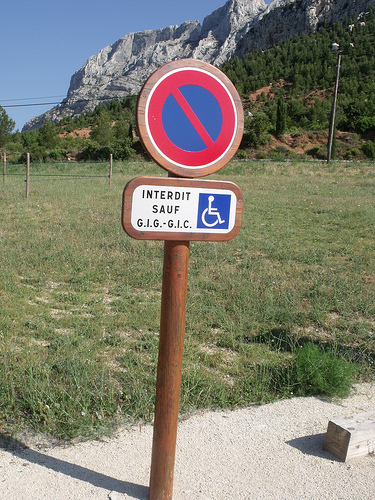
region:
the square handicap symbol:
[196, 187, 235, 231]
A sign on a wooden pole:
[99, 46, 254, 498]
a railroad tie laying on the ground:
[313, 386, 369, 464]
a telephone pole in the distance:
[312, 40, 346, 171]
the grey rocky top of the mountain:
[58, 15, 241, 75]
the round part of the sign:
[122, 48, 258, 178]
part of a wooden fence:
[3, 150, 118, 199]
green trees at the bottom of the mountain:
[262, 45, 325, 123]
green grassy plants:
[257, 324, 344, 397]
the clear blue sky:
[9, 14, 70, 78]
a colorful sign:
[122, 54, 248, 499]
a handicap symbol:
[198, 191, 231, 229]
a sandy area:
[214, 423, 317, 487]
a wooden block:
[322, 411, 373, 465]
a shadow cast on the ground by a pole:
[22, 444, 144, 499]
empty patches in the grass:
[209, 335, 236, 380]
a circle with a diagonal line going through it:
[133, 56, 244, 177]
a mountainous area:
[73, 6, 316, 43]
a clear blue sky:
[3, 3, 71, 81]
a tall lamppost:
[317, 36, 355, 161]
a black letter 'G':
[135, 217, 146, 228]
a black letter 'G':
[166, 218, 175, 228]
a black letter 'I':
[140, 189, 147, 197]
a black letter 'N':
[148, 189, 154, 198]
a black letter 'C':
[182, 218, 189, 231]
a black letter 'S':
[150, 201, 159, 214]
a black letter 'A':
[159, 205, 165, 214]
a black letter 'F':
[173, 205, 181, 213]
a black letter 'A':
[158, 201, 167, 213]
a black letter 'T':
[184, 191, 192, 200]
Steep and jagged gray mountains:
[71, 0, 322, 58]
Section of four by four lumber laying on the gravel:
[320, 404, 373, 464]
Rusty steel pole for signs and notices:
[157, 240, 192, 499]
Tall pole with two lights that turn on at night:
[325, 38, 358, 161]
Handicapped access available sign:
[197, 190, 233, 229]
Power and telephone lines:
[0, 91, 121, 110]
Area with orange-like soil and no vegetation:
[264, 129, 329, 153]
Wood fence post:
[23, 150, 33, 199]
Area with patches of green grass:
[14, 162, 108, 171]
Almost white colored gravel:
[197, 431, 306, 493]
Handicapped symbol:
[196, 192, 229, 228]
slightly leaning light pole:
[318, 32, 355, 161]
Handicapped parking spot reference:
[122, 175, 243, 240]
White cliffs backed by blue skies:
[58, 28, 120, 152]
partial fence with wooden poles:
[2, 149, 118, 188]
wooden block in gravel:
[324, 406, 374, 460]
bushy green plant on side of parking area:
[287, 333, 352, 398]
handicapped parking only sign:
[121, 55, 243, 242]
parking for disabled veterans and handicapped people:
[121, 174, 241, 240]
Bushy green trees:
[259, 42, 320, 120]